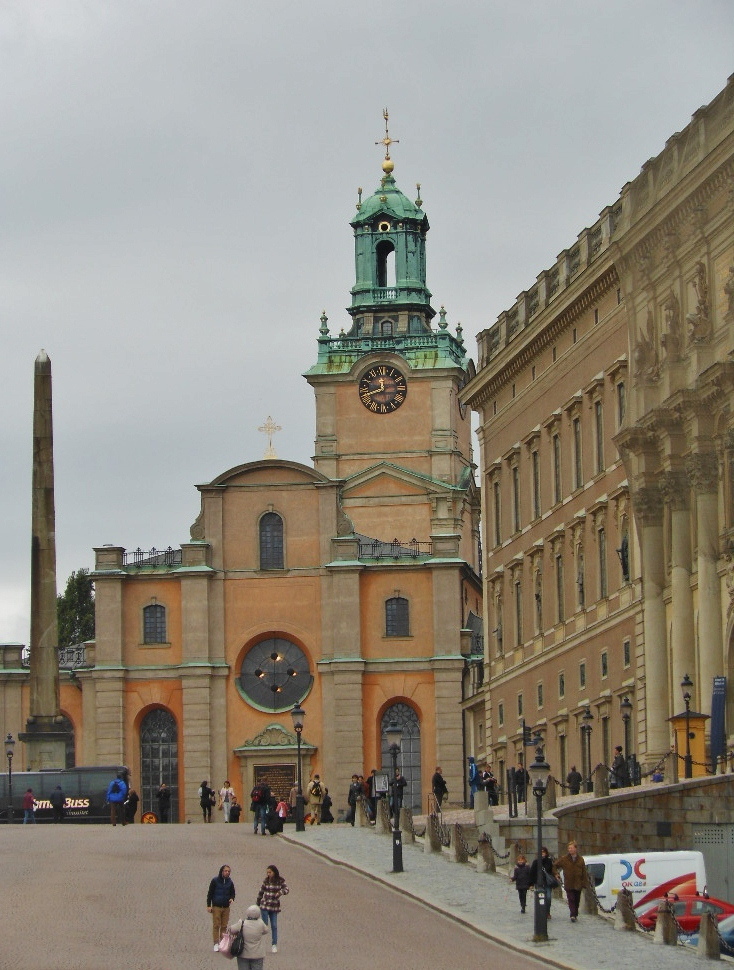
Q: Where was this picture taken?
A: In the street.